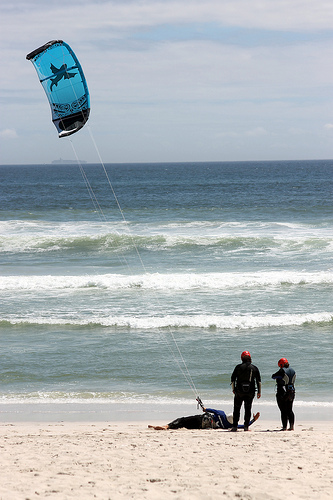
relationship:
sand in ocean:
[171, 431, 259, 460] [179, 322, 324, 358]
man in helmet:
[231, 350, 261, 433] [239, 348, 251, 358]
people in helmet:
[270, 356, 296, 432] [275, 356, 288, 365]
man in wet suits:
[148, 406, 261, 432] [227, 363, 258, 428]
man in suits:
[230, 350, 261, 433] [231, 367, 288, 421]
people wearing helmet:
[270, 356, 296, 432] [228, 343, 257, 362]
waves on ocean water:
[27, 208, 329, 346] [6, 164, 322, 392]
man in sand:
[148, 406, 261, 432] [2, 424, 327, 499]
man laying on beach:
[148, 406, 261, 432] [4, 395, 322, 490]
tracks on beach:
[20, 437, 312, 497] [1, 400, 321, 494]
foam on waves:
[7, 220, 325, 331] [8, 220, 322, 344]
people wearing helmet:
[270, 356, 296, 432] [274, 356, 290, 366]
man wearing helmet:
[230, 350, 261, 433] [238, 348, 252, 359]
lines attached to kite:
[66, 126, 170, 306] [22, 38, 94, 137]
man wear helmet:
[230, 350, 261, 433] [241, 350, 252, 361]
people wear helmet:
[269, 354, 304, 430] [278, 357, 289, 367]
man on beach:
[230, 350, 261, 433] [0, 404, 332, 498]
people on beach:
[270, 356, 296, 432] [0, 404, 332, 498]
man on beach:
[148, 406, 261, 432] [0, 404, 332, 498]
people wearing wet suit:
[270, 356, 296, 432] [270, 366, 297, 432]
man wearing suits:
[230, 350, 261, 433] [231, 362, 261, 427]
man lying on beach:
[146, 406, 261, 432] [0, 430, 330, 499]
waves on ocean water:
[0, 208, 329, 330] [0, 160, 333, 392]